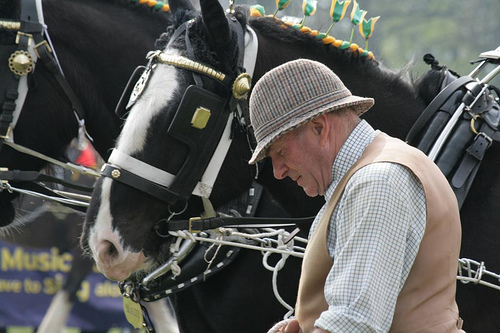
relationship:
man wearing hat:
[239, 57, 466, 330] [239, 47, 376, 160]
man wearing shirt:
[239, 57, 466, 330] [309, 118, 424, 331]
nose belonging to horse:
[79, 232, 124, 267] [78, 2, 458, 331]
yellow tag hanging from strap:
[110, 282, 155, 330] [116, 180, 261, 303]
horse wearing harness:
[78, 2, 458, 331] [94, 2, 271, 304]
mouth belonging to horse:
[108, 225, 160, 283] [78, 2, 458, 331]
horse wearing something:
[78, 2, 458, 331] [122, 27, 249, 108]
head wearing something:
[78, 1, 271, 294] [122, 27, 249, 108]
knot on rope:
[262, 229, 295, 273] [175, 217, 306, 317]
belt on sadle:
[194, 150, 229, 202] [402, 31, 497, 211]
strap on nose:
[104, 147, 175, 189] [82, 158, 174, 286]